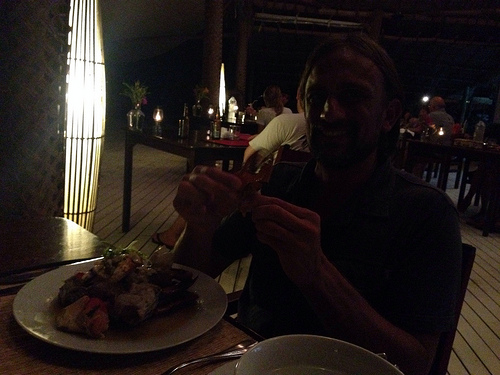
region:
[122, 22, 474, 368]
The man sitting nearest to the camera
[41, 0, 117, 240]
The light to the left of the nearest man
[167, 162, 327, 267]
The hands of the man nearest the camera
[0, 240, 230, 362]
The plate in front of the nearest man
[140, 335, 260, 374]
The utensil to the right of the plate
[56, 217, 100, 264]
The light reflecting off the table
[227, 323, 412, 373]
The bowl near the utensil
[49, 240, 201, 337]
The food on the nearest plate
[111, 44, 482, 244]
The people sitting in the background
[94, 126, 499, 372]
The floor shown behind the nearest man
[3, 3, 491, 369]
inside a dark restaurant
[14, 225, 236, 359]
food on top of white plate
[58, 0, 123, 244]
very bright white light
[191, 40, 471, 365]
man with food in his hands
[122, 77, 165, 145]
green plant in vase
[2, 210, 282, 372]
dark brown wooden table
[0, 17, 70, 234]
white hatched wooden fence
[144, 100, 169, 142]
clear wine glass with candle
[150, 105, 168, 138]
clear wine glass with light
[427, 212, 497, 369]
beige and black striped carpet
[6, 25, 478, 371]
a man in a dark room eating some tasty food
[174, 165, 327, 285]
a man's hands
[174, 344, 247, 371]
a handle of a silver utensil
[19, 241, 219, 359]
a plate of different types of meats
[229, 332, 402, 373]
a large bowl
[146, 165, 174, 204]
the floor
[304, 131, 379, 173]
a man's beard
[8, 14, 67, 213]
a lattice design on a wall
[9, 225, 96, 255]
a wooden table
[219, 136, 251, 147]
a red place mat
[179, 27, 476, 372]
A man that is smiling.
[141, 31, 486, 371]
A man that is sitting at a restaurant.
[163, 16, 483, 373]
A man eating some food.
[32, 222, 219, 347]
A plate of food on a white plate.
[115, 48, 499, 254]
People at tables eating in the background.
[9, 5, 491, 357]
Inside a restaurant.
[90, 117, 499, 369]
A white plank floors.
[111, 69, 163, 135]
A vase with a flower.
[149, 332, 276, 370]
A piece of silverware.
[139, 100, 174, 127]
A candle in a vase.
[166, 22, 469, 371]
Man sitting in a restaurant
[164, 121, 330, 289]
Two hands holding a piece of food.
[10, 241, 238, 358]
Dish is full of food.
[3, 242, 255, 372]
Utensils on side of white dish.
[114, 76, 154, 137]
Vase on border of table.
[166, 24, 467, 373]
Man is smiling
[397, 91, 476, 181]
Couple sitting by a table.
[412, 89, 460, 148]
Man is bald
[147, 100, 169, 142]
Candle is lit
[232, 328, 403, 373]
Empty bowl on table